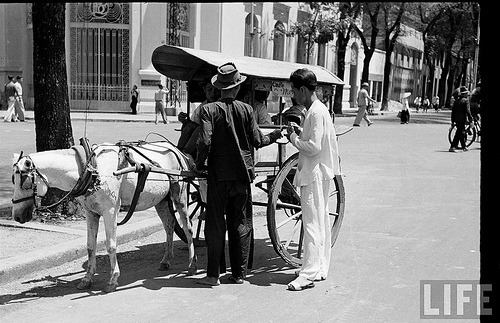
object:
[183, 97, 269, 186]
shirt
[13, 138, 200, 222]
harness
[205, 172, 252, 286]
pants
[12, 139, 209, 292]
horse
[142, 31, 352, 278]
wagon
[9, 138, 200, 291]
white horse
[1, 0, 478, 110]
building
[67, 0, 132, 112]
large window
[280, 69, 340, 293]
man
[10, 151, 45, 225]
head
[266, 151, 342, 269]
wheel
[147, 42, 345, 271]
cart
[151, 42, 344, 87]
roof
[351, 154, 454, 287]
road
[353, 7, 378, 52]
branches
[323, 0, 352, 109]
tree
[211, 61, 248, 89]
hat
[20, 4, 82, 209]
tree trunk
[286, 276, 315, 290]
shoes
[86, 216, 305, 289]
shadow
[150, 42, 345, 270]
buggy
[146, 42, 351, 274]
carriage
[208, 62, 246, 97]
head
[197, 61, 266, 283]
man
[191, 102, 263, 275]
suit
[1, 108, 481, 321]
street